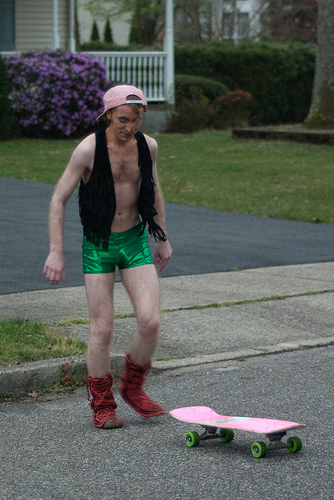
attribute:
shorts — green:
[81, 221, 153, 273]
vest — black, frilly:
[75, 129, 166, 252]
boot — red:
[84, 371, 123, 429]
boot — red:
[118, 352, 164, 418]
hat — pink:
[94, 85, 147, 120]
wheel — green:
[183, 431, 199, 446]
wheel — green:
[218, 428, 235, 442]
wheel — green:
[285, 435, 303, 455]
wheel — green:
[250, 439, 267, 459]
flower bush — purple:
[3, 46, 109, 135]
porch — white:
[1, 51, 164, 103]